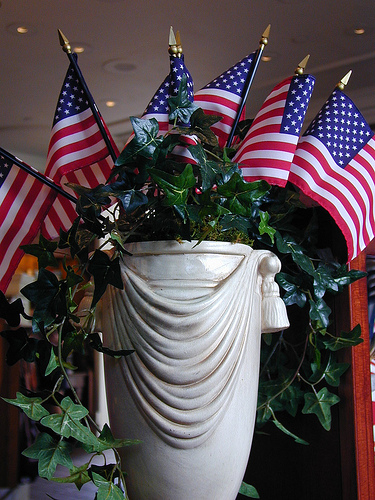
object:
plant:
[0, 82, 375, 395]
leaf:
[112, 189, 149, 213]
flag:
[193, 24, 272, 150]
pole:
[225, 25, 270, 156]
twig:
[192, 215, 220, 249]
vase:
[93, 241, 291, 500]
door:
[337, 128, 375, 500]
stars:
[233, 81, 239, 86]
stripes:
[217, 96, 233, 110]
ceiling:
[0, 1, 375, 150]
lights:
[16, 27, 29, 34]